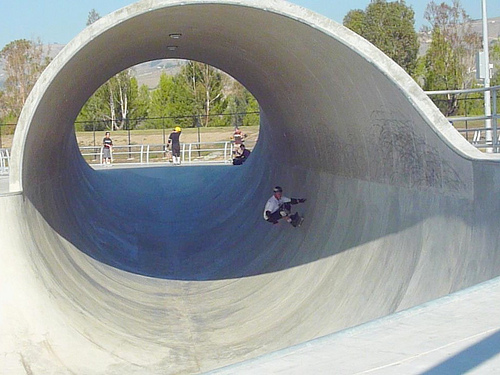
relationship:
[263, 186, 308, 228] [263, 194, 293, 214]
man wearing shirt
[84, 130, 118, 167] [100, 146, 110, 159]
man wearing short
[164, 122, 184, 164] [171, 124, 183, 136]
man wearing a helmet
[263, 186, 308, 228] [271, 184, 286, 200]
man wearing safety helmet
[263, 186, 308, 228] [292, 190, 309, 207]
man wearing glove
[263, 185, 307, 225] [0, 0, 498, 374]
man skateboarding in cement structure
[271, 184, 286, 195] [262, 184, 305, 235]
helmet on man